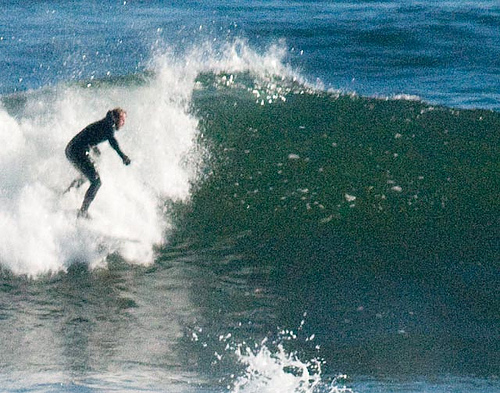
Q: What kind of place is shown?
A: It is an ocean.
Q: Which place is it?
A: It is an ocean.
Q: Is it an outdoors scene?
A: Yes, it is outdoors.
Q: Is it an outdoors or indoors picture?
A: It is outdoors.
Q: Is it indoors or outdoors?
A: It is outdoors.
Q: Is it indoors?
A: No, it is outdoors.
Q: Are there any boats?
A: No, there are no boats.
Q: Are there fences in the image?
A: No, there are no fences.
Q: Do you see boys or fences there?
A: No, there are no fences or boys.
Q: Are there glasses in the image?
A: No, there are no glasses.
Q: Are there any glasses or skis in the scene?
A: No, there are no glasses or skis.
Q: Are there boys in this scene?
A: No, there are no boys.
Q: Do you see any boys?
A: No, there are no boys.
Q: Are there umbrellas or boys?
A: No, there are no boys or umbrellas.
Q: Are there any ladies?
A: No, there are no ladies.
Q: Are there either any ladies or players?
A: No, there are no ladies or players.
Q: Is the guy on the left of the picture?
A: Yes, the guy is on the left of the image.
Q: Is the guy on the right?
A: No, the guy is on the left of the image.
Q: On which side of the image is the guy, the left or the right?
A: The guy is on the left of the image.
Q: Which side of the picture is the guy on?
A: The guy is on the left of the image.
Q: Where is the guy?
A: The guy is in the ocean.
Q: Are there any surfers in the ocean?
A: No, there is a guy in the ocean.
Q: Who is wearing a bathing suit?
A: The guy is wearing a bathing suit.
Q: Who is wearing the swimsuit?
A: The guy is wearing a bathing suit.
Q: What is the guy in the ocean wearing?
A: The guy is wearing a swimsuit.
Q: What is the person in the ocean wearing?
A: The guy is wearing a swimsuit.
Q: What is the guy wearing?
A: The guy is wearing a swimsuit.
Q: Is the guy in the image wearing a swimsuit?
A: Yes, the guy is wearing a swimsuit.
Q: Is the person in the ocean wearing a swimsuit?
A: Yes, the guy is wearing a swimsuit.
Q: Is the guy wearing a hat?
A: No, the guy is wearing a swimsuit.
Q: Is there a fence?
A: No, there are no fences.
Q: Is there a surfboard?
A: Yes, there is a surfboard.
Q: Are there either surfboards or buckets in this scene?
A: Yes, there is a surfboard.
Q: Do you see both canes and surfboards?
A: No, there is a surfboard but no canes.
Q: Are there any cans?
A: No, there are no cans.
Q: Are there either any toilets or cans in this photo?
A: No, there are no cans or toilets.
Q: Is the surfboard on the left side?
A: Yes, the surfboard is on the left of the image.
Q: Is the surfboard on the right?
A: No, the surfboard is on the left of the image.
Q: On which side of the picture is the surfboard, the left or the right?
A: The surfboard is on the left of the image.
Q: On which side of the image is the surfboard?
A: The surfboard is on the left of the image.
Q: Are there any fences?
A: No, there are no fences.